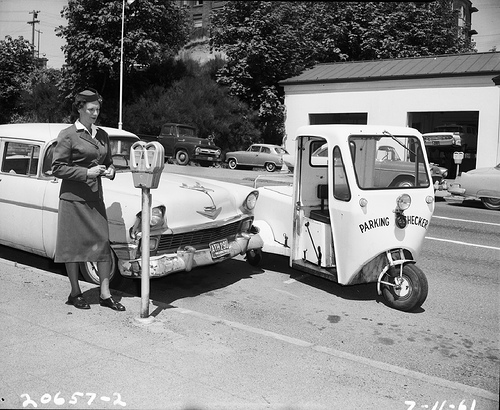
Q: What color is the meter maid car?
A: White.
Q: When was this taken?
A: Daytime.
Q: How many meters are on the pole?
A: 2.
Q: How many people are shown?
A: 1.